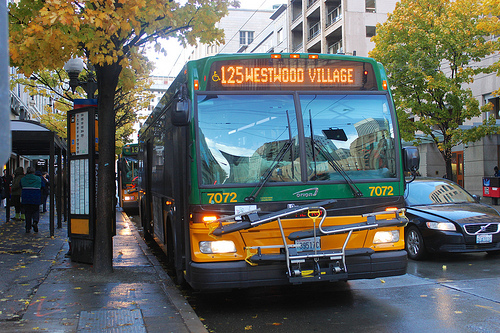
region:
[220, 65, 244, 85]
Numbers 125 on front of a bus.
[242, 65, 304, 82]
The word WESTWOOD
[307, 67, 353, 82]
The word VILLAGE on the front of a bus.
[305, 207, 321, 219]
Yellow handle on the front of a bus.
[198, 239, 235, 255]
Front headlight of a bus.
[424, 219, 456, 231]
Front headlight of a car.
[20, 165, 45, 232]
Person walking down sidewalk.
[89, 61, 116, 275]
Tall thin tree trunk.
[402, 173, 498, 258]
Car beside a bus.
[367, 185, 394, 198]
The number 7072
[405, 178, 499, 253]
Partial view of a Volvo car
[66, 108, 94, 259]
Bus route map and legend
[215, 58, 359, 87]
Number and name of the bus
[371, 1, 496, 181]
Tree along the side of the road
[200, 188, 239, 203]
bus number 7072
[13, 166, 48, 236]
man walking down the sidwalk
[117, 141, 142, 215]
Partial view of second bus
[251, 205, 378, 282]
bike rack on the front of the bus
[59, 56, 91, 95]
street lamp on top of a pole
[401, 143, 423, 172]
Driver's side mirror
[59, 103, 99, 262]
sign display with times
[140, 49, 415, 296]
green bus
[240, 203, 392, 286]
bike rack attached to front of bus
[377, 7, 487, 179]
tree with leaves truing yellow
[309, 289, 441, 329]
black asphalt wet with rain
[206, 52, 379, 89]
bus route displayed on the front of the bus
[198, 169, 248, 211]
bus I.D. number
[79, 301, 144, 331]
wet metal cover on the sidewalk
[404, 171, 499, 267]
black sedan with lights on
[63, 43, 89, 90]
street light not on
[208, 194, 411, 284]
bike rack on a bus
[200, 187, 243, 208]
yellow number on a bus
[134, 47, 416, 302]
green and yellow colored bus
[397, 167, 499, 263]
dark colored car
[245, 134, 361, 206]
windshield wipers on the bus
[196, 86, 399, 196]
windshield on the bus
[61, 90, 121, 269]
kiosk on the sidewalk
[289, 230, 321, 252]
front licence plate on the bus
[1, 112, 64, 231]
covered bus stop on the sidewalk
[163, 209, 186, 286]
front wheel of the bus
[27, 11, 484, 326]
Bus on busy city street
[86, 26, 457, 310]
Green and yellow bus on city street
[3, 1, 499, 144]
Early fall foliage on busy street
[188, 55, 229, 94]
Handicap accessible logo on green and yellow city bus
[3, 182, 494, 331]
city street after rain fall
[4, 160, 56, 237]
people walking on city street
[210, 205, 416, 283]
Bicycle rack on city bus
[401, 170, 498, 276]
Black car on congested city street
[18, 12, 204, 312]
Bus stopped on city street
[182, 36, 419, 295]
Bus number 125 to Westwood Village